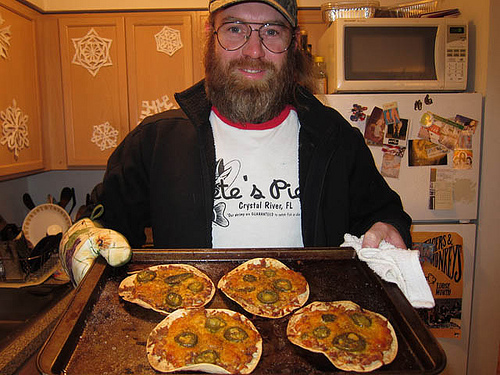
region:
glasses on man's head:
[197, 13, 307, 72]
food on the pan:
[100, 231, 400, 373]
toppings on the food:
[294, 294, 384, 367]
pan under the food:
[84, 308, 145, 374]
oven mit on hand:
[45, 188, 142, 291]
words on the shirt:
[193, 147, 314, 239]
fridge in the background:
[338, 102, 465, 181]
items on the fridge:
[365, 90, 490, 172]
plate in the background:
[23, 171, 91, 248]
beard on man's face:
[196, 53, 291, 128]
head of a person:
[198, 2, 316, 122]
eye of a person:
[219, 25, 254, 48]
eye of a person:
[256, 25, 285, 38]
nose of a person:
[235, 44, 285, 61]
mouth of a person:
[234, 62, 279, 78]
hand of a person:
[70, 210, 130, 280]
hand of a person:
[346, 208, 439, 264]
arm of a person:
[349, 140, 407, 217]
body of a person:
[137, 100, 351, 264]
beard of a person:
[223, 73, 281, 115]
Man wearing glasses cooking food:
[36, 0, 451, 374]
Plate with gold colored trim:
[18, 202, 73, 251]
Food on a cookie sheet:
[33, 242, 454, 374]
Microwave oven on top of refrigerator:
[310, 13, 484, 373]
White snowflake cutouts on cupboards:
[0, 0, 210, 182]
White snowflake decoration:
[66, 25, 116, 80]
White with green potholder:
[56, 200, 134, 299]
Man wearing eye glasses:
[60, 0, 413, 290]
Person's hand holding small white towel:
[337, 217, 438, 312]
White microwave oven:
[315, 0, 472, 95]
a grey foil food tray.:
[316, 0, 381, 20]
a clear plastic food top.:
[391, 0, 439, 19]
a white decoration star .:
[63, 27, 118, 77]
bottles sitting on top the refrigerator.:
[296, 26, 330, 93]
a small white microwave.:
[326, 15, 475, 97]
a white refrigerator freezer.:
[318, 92, 480, 222]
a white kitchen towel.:
[341, 227, 434, 312]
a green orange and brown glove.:
[56, 205, 131, 289]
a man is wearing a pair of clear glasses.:
[206, 12, 295, 56]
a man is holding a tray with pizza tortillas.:
[35, 0, 458, 374]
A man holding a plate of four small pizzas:
[61, 3, 441, 370]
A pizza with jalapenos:
[143, 306, 261, 373]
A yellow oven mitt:
[59, 218, 130, 281]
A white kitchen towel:
[341, 227, 431, 310]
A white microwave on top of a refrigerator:
[333, 19, 471, 94]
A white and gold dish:
[19, 200, 74, 249]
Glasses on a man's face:
[213, 18, 288, 54]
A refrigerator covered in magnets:
[329, 96, 479, 368]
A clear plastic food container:
[323, 3, 370, 20]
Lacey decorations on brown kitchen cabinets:
[56, 18, 211, 163]